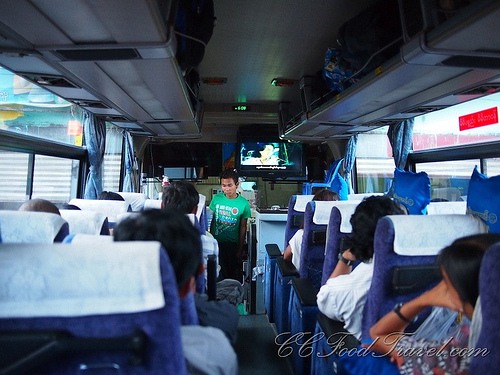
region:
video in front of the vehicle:
[236, 137, 288, 166]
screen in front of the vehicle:
[238, 138, 283, 167]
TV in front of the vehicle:
[237, 137, 283, 166]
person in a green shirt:
[210, 170, 252, 257]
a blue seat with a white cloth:
[0, 239, 184, 374]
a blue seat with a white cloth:
[358, 215, 488, 371]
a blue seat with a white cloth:
[0, 210, 67, 240]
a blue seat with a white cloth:
[116, 192, 147, 209]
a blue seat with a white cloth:
[55, 205, 110, 230]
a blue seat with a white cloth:
[286, 195, 306, 246]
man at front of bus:
[199, 172, 255, 280]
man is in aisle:
[205, 172, 299, 373]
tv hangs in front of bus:
[235, 135, 292, 174]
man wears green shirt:
[209, 192, 252, 244]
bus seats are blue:
[262, 165, 498, 373]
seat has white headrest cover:
[380, 217, 492, 257]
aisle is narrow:
[224, 304, 297, 374]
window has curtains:
[335, 120, 412, 200]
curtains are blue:
[337, 125, 413, 220]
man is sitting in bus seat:
[321, 198, 411, 360]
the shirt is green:
[197, 197, 262, 242]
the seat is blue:
[14, 230, 209, 370]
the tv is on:
[232, 127, 302, 184]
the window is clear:
[7, 88, 72, 143]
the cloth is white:
[320, 245, 375, 338]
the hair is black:
[218, 165, 241, 195]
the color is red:
[454, 107, 498, 136]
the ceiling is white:
[235, 27, 269, 97]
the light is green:
[232, 96, 254, 117]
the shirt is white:
[310, 247, 376, 342]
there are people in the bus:
[81, 123, 478, 317]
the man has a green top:
[213, 181, 252, 241]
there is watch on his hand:
[333, 249, 358, 272]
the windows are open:
[359, 155, 476, 197]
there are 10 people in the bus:
[39, 192, 479, 352]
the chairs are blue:
[292, 208, 354, 297]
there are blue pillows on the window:
[379, 162, 427, 204]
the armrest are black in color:
[293, 282, 318, 312]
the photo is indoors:
[0, 156, 479, 363]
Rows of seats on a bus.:
[264, 192, 498, 374]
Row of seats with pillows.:
[263, 162, 498, 373]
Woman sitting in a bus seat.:
[369, 230, 499, 374]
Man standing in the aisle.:
[205, 173, 251, 301]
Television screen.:
[234, 137, 302, 174]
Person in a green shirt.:
[205, 166, 252, 283]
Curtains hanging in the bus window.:
[81, 107, 143, 201]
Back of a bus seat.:
[1, 242, 186, 374]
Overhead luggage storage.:
[277, 47, 497, 144]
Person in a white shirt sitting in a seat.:
[316, 196, 405, 340]